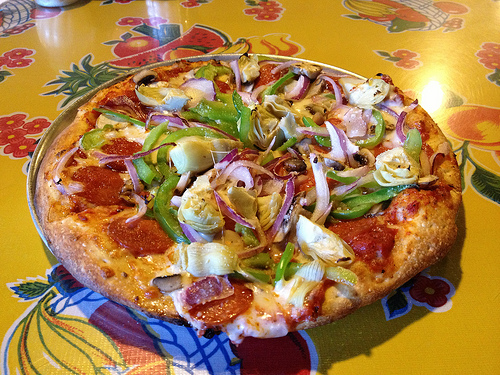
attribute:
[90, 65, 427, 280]
peppers — green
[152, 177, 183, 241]
pepper — green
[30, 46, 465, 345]
pizza — thin crust, small, round, gourmet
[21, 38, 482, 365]
pizza — pepperoni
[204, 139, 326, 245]
onions — white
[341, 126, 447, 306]
crust — brown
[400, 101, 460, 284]
crust — brown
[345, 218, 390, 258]
sauce — red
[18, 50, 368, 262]
pan — pizza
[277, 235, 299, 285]
pepper — green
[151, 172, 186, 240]
artichoke — sliced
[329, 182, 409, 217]
artichoke — sliced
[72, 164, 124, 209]
pepperoni — sliced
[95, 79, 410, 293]
toppings — several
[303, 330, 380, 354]
shadow — under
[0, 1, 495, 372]
tablecloth — yellow